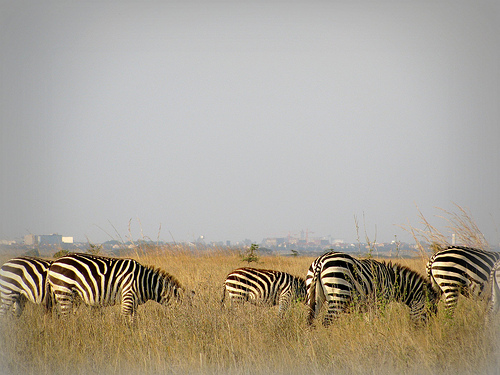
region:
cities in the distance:
[43, 224, 152, 253]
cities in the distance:
[183, 214, 310, 263]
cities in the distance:
[287, 233, 349, 255]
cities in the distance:
[370, 228, 424, 264]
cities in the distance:
[160, 233, 252, 258]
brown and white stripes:
[44, 234, 210, 325]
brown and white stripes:
[210, 224, 290, 318]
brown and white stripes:
[305, 247, 415, 329]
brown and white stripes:
[215, 262, 322, 320]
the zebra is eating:
[140, 259, 213, 342]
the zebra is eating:
[266, 266, 343, 339]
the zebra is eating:
[409, 268, 460, 363]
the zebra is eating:
[170, 253, 216, 333]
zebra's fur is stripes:
[33, 239, 226, 361]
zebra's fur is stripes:
[178, 249, 334, 340]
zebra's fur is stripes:
[318, 248, 443, 349]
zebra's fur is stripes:
[53, 233, 145, 305]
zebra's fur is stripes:
[391, 228, 497, 346]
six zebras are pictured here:
[8, 240, 493, 340]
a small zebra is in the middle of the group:
[217, 250, 307, 331]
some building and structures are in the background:
[2, 215, 492, 252]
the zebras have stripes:
[6, 245, 496, 327]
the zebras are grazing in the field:
[6, 246, 491, 321]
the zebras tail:
[300, 250, 320, 342]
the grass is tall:
[46, 306, 487, 373]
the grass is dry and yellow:
[69, 318, 354, 373]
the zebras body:
[61, 260, 128, 305]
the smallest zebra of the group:
[211, 260, 311, 325]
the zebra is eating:
[40, 243, 184, 329]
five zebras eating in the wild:
[17, 228, 489, 359]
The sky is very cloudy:
[94, 140, 326, 182]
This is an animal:
[55, 221, 410, 356]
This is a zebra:
[50, 212, 375, 352]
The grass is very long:
[216, 323, 288, 363]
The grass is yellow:
[158, 281, 208, 368]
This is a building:
[29, 231, 94, 263]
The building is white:
[12, 218, 110, 256]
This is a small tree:
[205, 236, 265, 258]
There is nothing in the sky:
[191, 159, 447, 244]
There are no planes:
[297, 130, 433, 195]